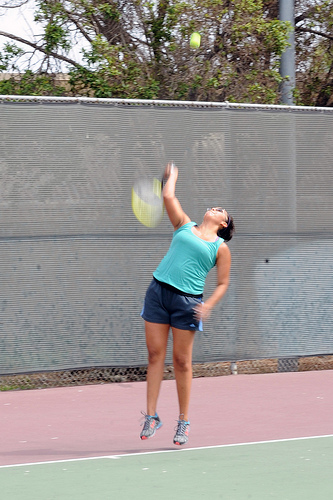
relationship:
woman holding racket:
[138, 161, 235, 446] [128, 157, 173, 232]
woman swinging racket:
[138, 161, 235, 446] [128, 157, 173, 232]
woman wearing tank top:
[138, 161, 235, 446] [150, 218, 224, 296]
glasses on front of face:
[205, 205, 223, 214] [205, 203, 227, 219]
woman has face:
[138, 161, 235, 446] [205, 203, 227, 219]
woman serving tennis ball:
[138, 161, 235, 446] [185, 29, 201, 52]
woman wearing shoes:
[138, 161, 235, 446] [137, 410, 191, 448]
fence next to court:
[0, 94, 332, 389] [0, 368, 331, 499]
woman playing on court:
[138, 161, 235, 446] [0, 368, 331, 499]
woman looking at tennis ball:
[138, 161, 235, 446] [185, 29, 201, 52]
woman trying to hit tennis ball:
[138, 161, 235, 446] [185, 29, 201, 52]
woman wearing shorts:
[138, 161, 235, 446] [140, 277, 205, 331]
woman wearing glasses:
[138, 161, 235, 446] [205, 205, 223, 214]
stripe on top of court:
[1, 432, 332, 468] [0, 368, 331, 499]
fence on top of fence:
[0, 94, 333, 382] [0, 94, 332, 389]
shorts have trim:
[140, 277, 205, 331] [196, 296, 204, 334]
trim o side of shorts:
[196, 296, 204, 334] [140, 277, 205, 331]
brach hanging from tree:
[1, 27, 91, 75] [1, 1, 286, 107]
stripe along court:
[1, 432, 332, 468] [0, 368, 331, 499]